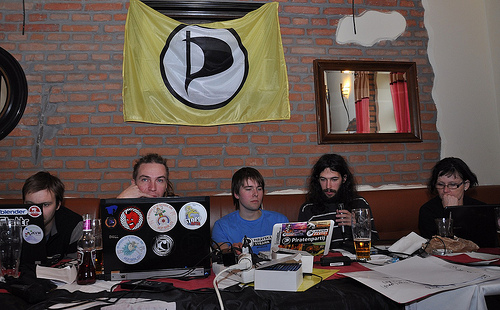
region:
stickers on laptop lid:
[105, 200, 208, 266]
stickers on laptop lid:
[272, 223, 330, 246]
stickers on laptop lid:
[26, 207, 44, 254]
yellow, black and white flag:
[116, 2, 292, 121]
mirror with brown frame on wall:
[314, 58, 423, 145]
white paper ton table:
[371, 262, 458, 289]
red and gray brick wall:
[36, 17, 118, 162]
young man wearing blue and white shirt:
[218, 210, 273, 235]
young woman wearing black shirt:
[462, 207, 492, 233]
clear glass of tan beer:
[349, 203, 378, 258]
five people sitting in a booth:
[13, 138, 488, 280]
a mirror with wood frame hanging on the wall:
[305, 45, 430, 153]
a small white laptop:
[259, 210, 336, 272]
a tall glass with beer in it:
[349, 201, 376, 258]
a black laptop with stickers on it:
[97, 191, 214, 280]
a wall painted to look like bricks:
[8, 5, 492, 197]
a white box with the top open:
[252, 248, 309, 293]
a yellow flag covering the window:
[113, 0, 303, 139]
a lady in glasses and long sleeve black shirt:
[414, 155, 499, 256]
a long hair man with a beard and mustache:
[297, 150, 368, 213]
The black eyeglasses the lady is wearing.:
[433, 177, 462, 190]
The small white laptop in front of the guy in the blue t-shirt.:
[267, 219, 332, 261]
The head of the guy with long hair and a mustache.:
[304, 152, 361, 202]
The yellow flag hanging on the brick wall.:
[124, 3, 300, 127]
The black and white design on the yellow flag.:
[147, 16, 264, 113]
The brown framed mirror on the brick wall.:
[312, 56, 424, 141]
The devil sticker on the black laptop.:
[119, 208, 140, 230]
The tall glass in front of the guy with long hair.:
[347, 207, 376, 259]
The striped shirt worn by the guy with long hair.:
[292, 200, 378, 247]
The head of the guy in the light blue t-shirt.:
[227, 170, 276, 215]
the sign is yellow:
[121, 3, 298, 130]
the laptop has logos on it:
[96, 196, 234, 280]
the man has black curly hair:
[296, 136, 360, 200]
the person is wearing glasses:
[429, 144, 477, 212]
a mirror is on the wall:
[301, 39, 453, 146]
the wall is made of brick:
[3, 1, 480, 179]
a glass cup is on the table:
[343, 205, 396, 285]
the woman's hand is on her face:
[428, 149, 480, 241]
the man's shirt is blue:
[198, 196, 313, 263]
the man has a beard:
[298, 149, 365, 220]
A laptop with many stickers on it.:
[100, 197, 212, 279]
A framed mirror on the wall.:
[312, 58, 422, 140]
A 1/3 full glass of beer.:
[352, 211, 373, 258]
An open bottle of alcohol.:
[75, 216, 97, 286]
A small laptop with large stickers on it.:
[273, 220, 333, 257]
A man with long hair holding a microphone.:
[296, 151, 378, 246]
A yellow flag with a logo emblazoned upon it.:
[123, 1, 293, 126]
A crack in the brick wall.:
[28, 86, 58, 165]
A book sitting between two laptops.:
[36, 250, 80, 285]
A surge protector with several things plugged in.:
[208, 243, 255, 285]